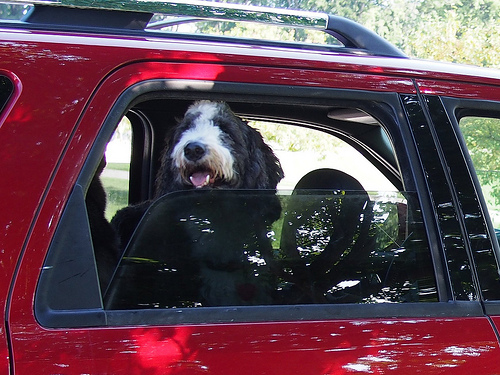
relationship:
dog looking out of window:
[160, 106, 300, 267] [101, 107, 421, 305]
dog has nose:
[160, 106, 300, 267] [184, 144, 198, 163]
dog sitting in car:
[160, 106, 300, 267] [15, 23, 490, 350]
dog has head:
[160, 106, 300, 267] [177, 113, 247, 190]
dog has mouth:
[160, 106, 300, 267] [186, 168, 218, 191]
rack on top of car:
[13, 7, 406, 62] [15, 23, 490, 350]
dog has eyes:
[160, 106, 300, 267] [183, 121, 235, 138]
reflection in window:
[274, 222, 390, 287] [101, 107, 421, 305]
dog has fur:
[160, 106, 300, 267] [222, 121, 264, 179]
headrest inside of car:
[287, 180, 368, 252] [15, 23, 490, 350]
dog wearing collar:
[160, 106, 300, 267] [199, 254, 258, 273]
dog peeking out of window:
[160, 106, 300, 267] [101, 107, 421, 305]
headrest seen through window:
[287, 180, 368, 252] [101, 107, 421, 305]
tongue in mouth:
[195, 173, 203, 185] [186, 168, 218, 191]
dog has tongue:
[160, 106, 300, 267] [195, 173, 203, 185]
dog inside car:
[160, 106, 300, 267] [15, 23, 490, 350]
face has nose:
[175, 122, 244, 186] [184, 144, 198, 163]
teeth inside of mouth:
[202, 173, 210, 187] [186, 168, 218, 191]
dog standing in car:
[160, 106, 300, 267] [15, 23, 490, 350]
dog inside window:
[160, 106, 300, 267] [101, 107, 421, 305]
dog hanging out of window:
[160, 106, 300, 267] [101, 107, 421, 305]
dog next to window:
[160, 106, 300, 267] [101, 107, 421, 305]